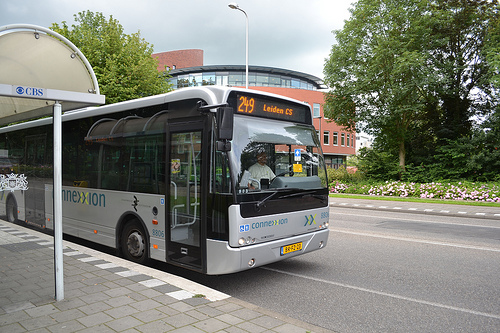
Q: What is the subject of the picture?
A: A bus.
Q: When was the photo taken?
A: Daytime.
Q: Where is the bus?
A: At a bus stop.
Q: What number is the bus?
A: 219.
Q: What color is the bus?
A: Silver and blue.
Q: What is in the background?
A: A building, plants and trees.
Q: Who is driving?
A: A bus driver.